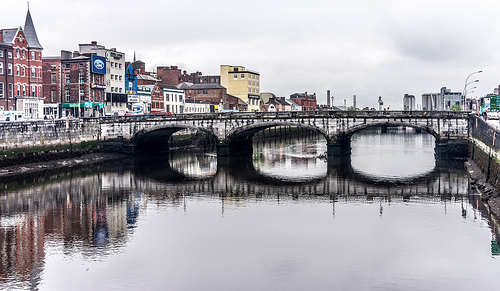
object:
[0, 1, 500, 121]
buildings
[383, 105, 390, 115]
people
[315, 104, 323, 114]
people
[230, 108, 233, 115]
people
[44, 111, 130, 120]
people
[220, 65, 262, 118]
yellow building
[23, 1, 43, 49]
roof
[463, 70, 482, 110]
light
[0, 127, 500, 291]
river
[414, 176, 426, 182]
ground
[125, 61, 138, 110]
blue building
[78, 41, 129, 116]
white building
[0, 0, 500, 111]
clouds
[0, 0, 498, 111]
sky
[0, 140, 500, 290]
reflection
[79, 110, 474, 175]
bridge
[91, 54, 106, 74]
sign